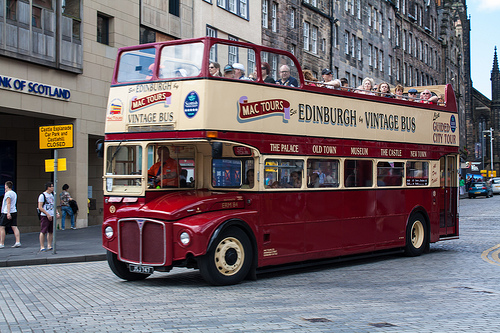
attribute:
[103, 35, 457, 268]
bus — double decker, large, vintage, red, beige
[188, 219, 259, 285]
wheel — metal, large, black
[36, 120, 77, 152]
sign — yellow, large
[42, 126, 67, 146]
letters — black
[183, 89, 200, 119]
decal — blue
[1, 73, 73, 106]
words — blue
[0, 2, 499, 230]
buildings — tan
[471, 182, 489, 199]
car — parked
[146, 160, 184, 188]
shirt — red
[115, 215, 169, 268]
grate — silver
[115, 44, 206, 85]
window — large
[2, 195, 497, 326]
tiles — blue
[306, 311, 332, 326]
spot — black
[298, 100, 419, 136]
lettering — green